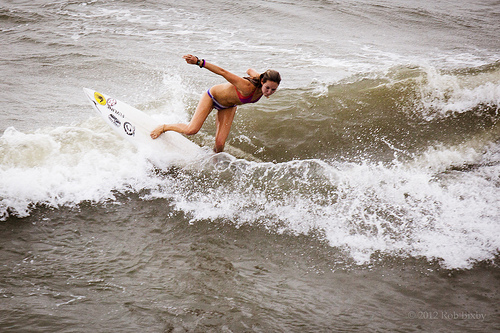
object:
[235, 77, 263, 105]
bikini top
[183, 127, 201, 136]
knee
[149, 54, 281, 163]
woman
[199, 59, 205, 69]
wristbands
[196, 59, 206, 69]
wrist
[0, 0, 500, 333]
ocean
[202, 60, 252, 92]
arm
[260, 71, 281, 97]
head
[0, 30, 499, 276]
wave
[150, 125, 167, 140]
foot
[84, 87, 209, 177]
surfboard